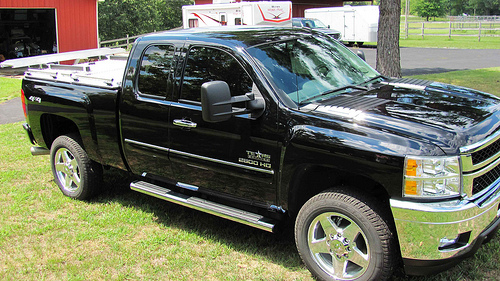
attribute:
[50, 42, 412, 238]
truck — black, a pick up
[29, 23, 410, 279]
truck — pick-up, black 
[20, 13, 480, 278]
truck — pick up, large, black, pick-up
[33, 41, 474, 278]
truck — large, black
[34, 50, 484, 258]
truck — black, large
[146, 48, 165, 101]
window — side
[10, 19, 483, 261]
truck — pick up, big, black, large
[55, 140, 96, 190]
wheel — back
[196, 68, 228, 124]
side mirror — black